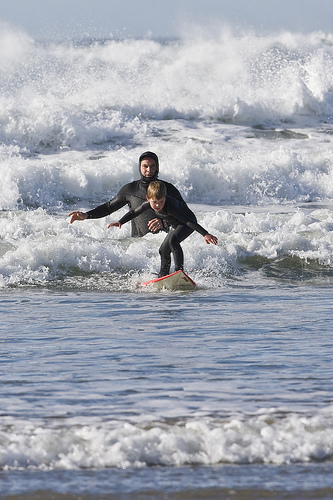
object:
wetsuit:
[116, 199, 207, 276]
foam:
[0, 411, 333, 475]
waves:
[0, 13, 332, 142]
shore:
[0, 458, 333, 500]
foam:
[28, 57, 214, 146]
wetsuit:
[82, 178, 184, 230]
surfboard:
[138, 269, 199, 289]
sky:
[0, 0, 332, 39]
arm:
[167, 206, 208, 238]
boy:
[105, 177, 219, 279]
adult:
[67, 149, 197, 238]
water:
[0, 21, 333, 500]